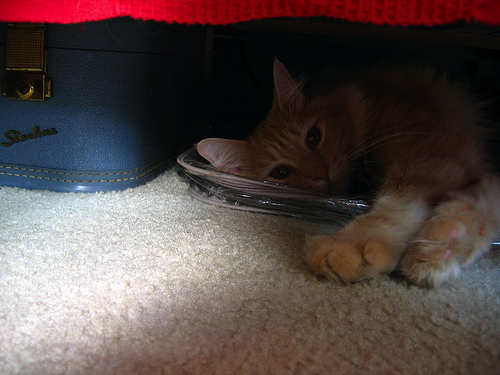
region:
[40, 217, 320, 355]
Synthetic fiber carpet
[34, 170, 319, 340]
Beige carpet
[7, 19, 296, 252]
A suitcase on the floor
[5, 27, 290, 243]
Blue luggage with golden hardware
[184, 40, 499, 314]
Cat sleeping on the carpet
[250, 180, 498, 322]
Paws of a cat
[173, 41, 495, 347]
Cat on a plastic bag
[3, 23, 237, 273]
Blue luggage with stitched edge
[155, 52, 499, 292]
Cat looking at the camera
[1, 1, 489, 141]
Red cloth over luggage and cat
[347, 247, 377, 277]
paws of a cat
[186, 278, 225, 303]
section of a surface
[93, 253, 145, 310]
part of a carpet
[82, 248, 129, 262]
part of a white floor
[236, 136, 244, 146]
ear of a cat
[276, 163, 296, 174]
eye of a cat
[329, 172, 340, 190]
mouth of a cat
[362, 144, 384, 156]
hair of a cat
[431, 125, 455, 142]
body of a cat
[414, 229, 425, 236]
front limb of a cat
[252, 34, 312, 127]
ear on a cat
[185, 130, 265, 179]
ear on a cat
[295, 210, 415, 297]
furry paw on a cat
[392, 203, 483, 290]
furry paw on a cat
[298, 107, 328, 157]
large eye on a cat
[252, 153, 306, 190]
large eye on a cat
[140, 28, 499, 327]
cat laying on a carpet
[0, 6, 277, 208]
large blue suitcase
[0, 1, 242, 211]
suitcase is rather old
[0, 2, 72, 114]
metal buckle on suitcase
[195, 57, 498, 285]
a cat by a blue piece of luggage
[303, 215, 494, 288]
front paws of the cat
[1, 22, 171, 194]
part of a blue suitcase by the kit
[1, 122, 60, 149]
word in black on the blue suitcase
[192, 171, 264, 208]
part of plastic the cat is laying on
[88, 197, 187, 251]
white carpet by the suitcase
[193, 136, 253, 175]
one of the cat's ears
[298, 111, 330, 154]
one of the eyes of the cat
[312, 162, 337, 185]
nose of the cat laying by the suitcase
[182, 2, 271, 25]
part of the hem of red fabric over the cat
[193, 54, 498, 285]
The cat is orange and white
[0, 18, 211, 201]
The case is blue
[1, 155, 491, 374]
The carpet is cream colored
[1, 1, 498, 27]
A red blanket hangs over the cats head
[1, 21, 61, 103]
The case has gold latches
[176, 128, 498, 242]
the cat is laying on clear plastic bag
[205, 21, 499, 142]
A case is shadowed behind the cat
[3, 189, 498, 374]
The carpet has a shadow cast on it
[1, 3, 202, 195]
Blue case is a hard case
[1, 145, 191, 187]
Blue case has white stitching